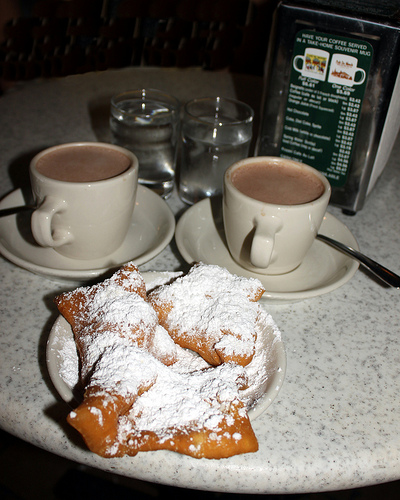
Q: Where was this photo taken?
A: In a restaurant.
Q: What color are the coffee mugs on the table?
A: White.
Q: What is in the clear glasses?
A: Water.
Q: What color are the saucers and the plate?
A: White.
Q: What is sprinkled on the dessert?
A: Powdered sugar.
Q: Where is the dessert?
A: In the foreground, on the table.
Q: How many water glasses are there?
A: Two.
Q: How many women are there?
A: Zero.